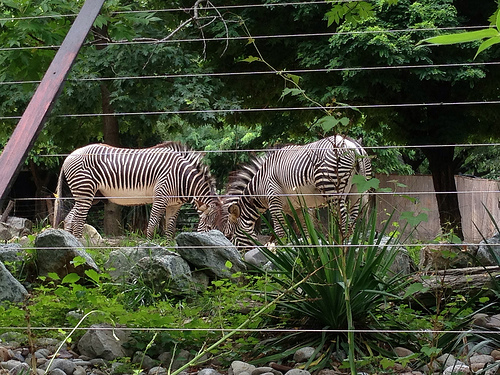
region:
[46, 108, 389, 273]
Two zebras in a zoo.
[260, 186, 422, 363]
A flower near the fence.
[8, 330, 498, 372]
Gravels lying near the fence.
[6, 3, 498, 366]
A large zoo fence.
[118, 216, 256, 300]
Several rocks on the ground.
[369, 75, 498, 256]
A large tree in the background.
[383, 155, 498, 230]
A wooden fence lining the back of the property.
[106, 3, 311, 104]
A branch hanging down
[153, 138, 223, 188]
The zebra's mane on its neck.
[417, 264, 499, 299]
A log on the ground.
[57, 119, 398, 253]
Two zebras in the zoo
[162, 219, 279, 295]
Large rocks on the ground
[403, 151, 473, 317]
Trees in front of a fence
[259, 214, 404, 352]
Crab grass on the ground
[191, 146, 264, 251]
Zebras with there head down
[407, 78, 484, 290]
Trees in front of a fence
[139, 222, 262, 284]
Rocks in front of a zebra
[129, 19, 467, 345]
Fence in front of zebras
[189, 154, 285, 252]
Zebras eating grass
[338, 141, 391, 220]
Zebras with a bushy tail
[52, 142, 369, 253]
Two zebras standing across from each other looking down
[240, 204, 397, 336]
Thick green bush near rocks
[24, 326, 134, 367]
A pile of small dark gray rocks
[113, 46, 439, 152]
Thin gray metal wire fence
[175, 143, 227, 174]
Black and white striped zebra's mane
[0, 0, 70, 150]
Discolored wooden post of a wire fence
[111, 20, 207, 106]
Large dark green leaves of a tree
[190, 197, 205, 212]
Small outward pointing striped ear of a zebra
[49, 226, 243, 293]
Large gray rocks standing upright in grass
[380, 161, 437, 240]
Tall gray wall standing near trees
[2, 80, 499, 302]
two zebras in a zoo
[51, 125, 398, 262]
two zebras eating grass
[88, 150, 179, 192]
the stripes of a zebra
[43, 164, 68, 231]
the tail of a zebra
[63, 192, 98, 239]
the rear legs of a zebra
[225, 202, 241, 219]
the ear of a zebra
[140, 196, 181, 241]
the front legs of a zebra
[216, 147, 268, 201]
the mane of a zebra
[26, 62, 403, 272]
two zebras in a zoo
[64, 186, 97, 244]
the rear legs of a zebra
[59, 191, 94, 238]
the back legs of a zebra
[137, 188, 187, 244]
the front legs of a zebra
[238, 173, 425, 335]
an agave plant